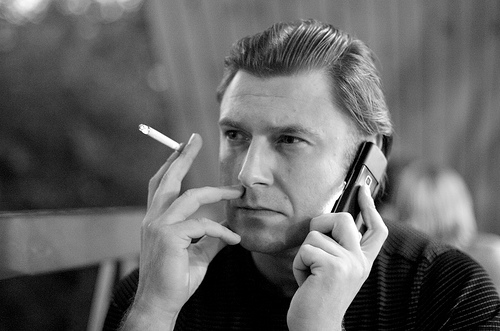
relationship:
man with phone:
[112, 15, 494, 328] [330, 140, 388, 247]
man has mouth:
[112, 15, 494, 328] [227, 198, 288, 225]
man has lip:
[112, 15, 494, 328] [233, 201, 284, 217]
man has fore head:
[112, 15, 494, 328] [219, 73, 316, 118]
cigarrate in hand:
[134, 122, 187, 153] [124, 132, 268, 294]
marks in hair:
[282, 23, 349, 68] [216, 22, 389, 137]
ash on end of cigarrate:
[137, 118, 147, 138] [134, 122, 187, 153]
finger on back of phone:
[151, 132, 389, 259] [332, 133, 399, 243]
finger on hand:
[151, 132, 389, 259] [114, 127, 258, 297]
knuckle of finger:
[330, 205, 364, 233] [151, 132, 389, 259]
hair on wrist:
[216, 22, 389, 137] [106, 293, 184, 329]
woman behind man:
[391, 166, 492, 242] [112, 15, 494, 328]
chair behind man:
[71, 233, 158, 309] [112, 15, 494, 328]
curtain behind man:
[143, 4, 498, 223] [112, 15, 494, 328]